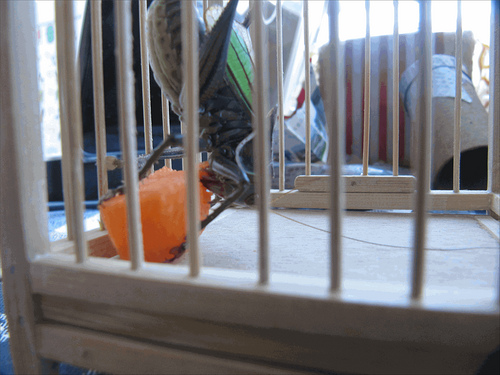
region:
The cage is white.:
[28, 25, 498, 329]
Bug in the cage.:
[147, 6, 280, 222]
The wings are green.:
[202, 7, 275, 125]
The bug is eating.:
[155, 117, 263, 239]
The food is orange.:
[109, 157, 206, 258]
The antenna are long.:
[254, 166, 463, 261]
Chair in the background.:
[321, 24, 475, 181]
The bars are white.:
[160, 77, 458, 297]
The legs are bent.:
[171, 11, 248, 115]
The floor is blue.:
[1, 176, 117, 373]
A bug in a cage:
[155, 0, 310, 201]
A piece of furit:
[100, 170, 228, 252]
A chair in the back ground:
[331, 7, 483, 174]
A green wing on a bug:
[195, 12, 270, 118]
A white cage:
[322, 57, 482, 317]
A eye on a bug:
[235, 185, 260, 210]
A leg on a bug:
[170, 185, 250, 255]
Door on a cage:
[276, 31, 436, 186]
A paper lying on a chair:
[275, 100, 327, 170]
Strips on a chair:
[342, 36, 423, 151]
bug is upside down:
[100, 0, 499, 263]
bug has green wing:
[227, 23, 256, 115]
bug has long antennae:
[269, 208, 496, 250]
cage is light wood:
[0, 1, 498, 374]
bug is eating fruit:
[98, 161, 212, 264]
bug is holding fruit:
[99, 159, 215, 264]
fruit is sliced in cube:
[95, 161, 215, 265]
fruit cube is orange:
[98, 160, 213, 262]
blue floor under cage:
[0, 201, 101, 374]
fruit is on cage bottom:
[55, 167, 497, 297]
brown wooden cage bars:
[323, 6, 433, 306]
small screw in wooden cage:
[62, 340, 98, 365]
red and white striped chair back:
[332, 35, 397, 160]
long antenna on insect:
[275, 201, 490, 262]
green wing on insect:
[227, 37, 254, 95]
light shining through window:
[298, 0, 477, 30]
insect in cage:
[88, 1, 340, 278]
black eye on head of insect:
[240, 181, 264, 221]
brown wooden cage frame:
[0, 0, 53, 365]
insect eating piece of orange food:
[83, 11, 316, 288]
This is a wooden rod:
[407, 5, 438, 307]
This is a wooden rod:
[442, 5, 473, 206]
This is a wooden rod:
[387, 5, 407, 186]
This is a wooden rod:
[357, 2, 381, 174]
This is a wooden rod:
[318, 10, 352, 307]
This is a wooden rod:
[287, 5, 319, 183]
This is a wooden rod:
[267, 1, 294, 199]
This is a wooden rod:
[242, 0, 283, 291]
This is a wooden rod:
[175, 2, 210, 289]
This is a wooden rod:
[102, 4, 157, 282]